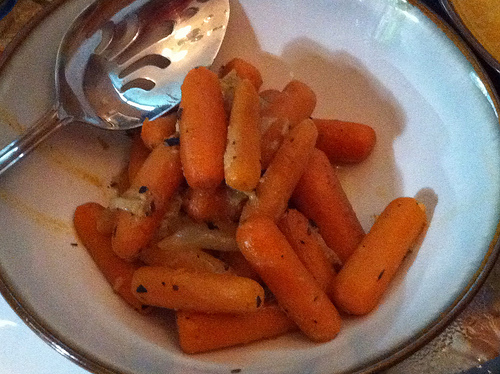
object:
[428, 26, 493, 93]
trim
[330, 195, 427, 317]
carrot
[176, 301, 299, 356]
carrot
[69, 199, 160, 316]
carrot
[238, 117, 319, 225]
carrot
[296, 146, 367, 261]
carrot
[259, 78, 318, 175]
carrot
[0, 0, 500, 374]
ground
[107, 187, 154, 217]
onion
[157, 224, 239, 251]
onion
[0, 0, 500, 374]
table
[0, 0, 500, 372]
bowl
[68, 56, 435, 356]
food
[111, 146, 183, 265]
carrot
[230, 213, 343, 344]
carrot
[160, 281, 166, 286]
stuff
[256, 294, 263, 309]
stuff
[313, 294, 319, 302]
stuff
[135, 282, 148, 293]
black pepper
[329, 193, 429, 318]
baby carrot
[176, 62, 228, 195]
baby carrot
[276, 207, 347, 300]
orange piece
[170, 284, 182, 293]
flakes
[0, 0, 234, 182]
spoon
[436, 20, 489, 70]
utensil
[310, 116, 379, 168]
carrot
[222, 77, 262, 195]
carrot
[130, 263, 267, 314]
carrot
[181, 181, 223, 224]
carrot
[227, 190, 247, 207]
onions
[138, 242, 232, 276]
riding boot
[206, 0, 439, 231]
shadow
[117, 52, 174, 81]
hole